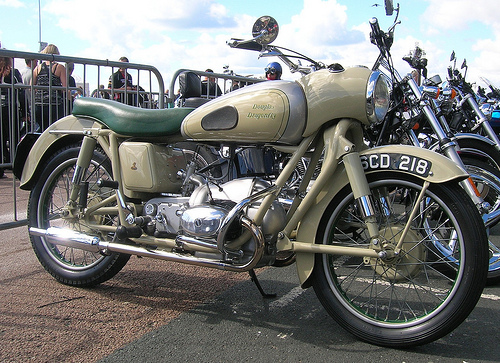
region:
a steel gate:
[0, 43, 245, 233]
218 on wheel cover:
[396, 154, 430, 174]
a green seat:
[69, 92, 192, 138]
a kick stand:
[243, 268, 278, 308]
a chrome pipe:
[26, 224, 100, 249]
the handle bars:
[223, 0, 403, 69]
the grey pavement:
[3, 171, 498, 361]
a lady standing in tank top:
[28, 42, 74, 124]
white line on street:
[259, 256, 499, 340]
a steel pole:
[36, 0, 43, 45]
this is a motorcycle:
[9, 9, 463, 344]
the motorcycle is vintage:
[45, 75, 391, 264]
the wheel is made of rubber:
[329, 190, 486, 350]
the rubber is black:
[279, 164, 469, 304]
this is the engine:
[145, 159, 289, 255]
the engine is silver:
[172, 175, 303, 286]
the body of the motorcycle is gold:
[205, 79, 380, 161]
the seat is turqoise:
[72, 97, 178, 132]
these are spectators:
[10, 44, 168, 129]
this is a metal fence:
[13, 54, 126, 109]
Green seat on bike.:
[86, 94, 181, 136]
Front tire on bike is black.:
[326, 208, 429, 353]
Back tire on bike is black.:
[12, 190, 127, 310]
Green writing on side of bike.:
[238, 97, 313, 147]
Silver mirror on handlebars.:
[248, 10, 288, 50]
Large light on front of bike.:
[363, 76, 398, 116]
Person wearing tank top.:
[48, 80, 63, 101]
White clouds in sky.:
[286, 13, 346, 33]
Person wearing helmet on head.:
[258, 58, 281, 79]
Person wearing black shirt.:
[105, 70, 140, 90]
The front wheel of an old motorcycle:
[321, 146, 499, 351]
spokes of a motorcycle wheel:
[424, 231, 451, 277]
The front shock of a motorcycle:
[333, 138, 394, 256]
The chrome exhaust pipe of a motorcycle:
[23, 219, 120, 258]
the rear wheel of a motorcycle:
[8, 129, 145, 291]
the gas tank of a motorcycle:
[169, 73, 310, 154]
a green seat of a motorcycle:
[67, 89, 198, 142]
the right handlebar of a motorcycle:
[226, 25, 308, 83]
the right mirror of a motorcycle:
[245, 25, 288, 53]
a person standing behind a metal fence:
[28, 39, 73, 141]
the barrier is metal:
[1, 50, 161, 219]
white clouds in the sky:
[75, 8, 191, 55]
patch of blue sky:
[228, 5, 319, 26]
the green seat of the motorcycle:
[65, 86, 182, 141]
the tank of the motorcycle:
[185, 70, 307, 145]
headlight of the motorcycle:
[355, 72, 397, 118]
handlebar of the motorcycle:
[345, 7, 410, 67]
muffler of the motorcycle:
[10, 215, 265, 272]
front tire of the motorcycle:
[315, 148, 489, 349]